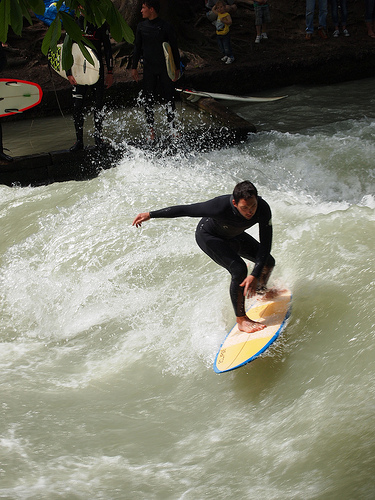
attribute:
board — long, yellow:
[217, 286, 295, 376]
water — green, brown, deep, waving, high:
[0, 123, 367, 494]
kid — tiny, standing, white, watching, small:
[210, 4, 240, 66]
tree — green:
[0, 0, 139, 75]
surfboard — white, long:
[35, 40, 106, 101]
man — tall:
[135, 178, 284, 332]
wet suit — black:
[153, 197, 273, 304]